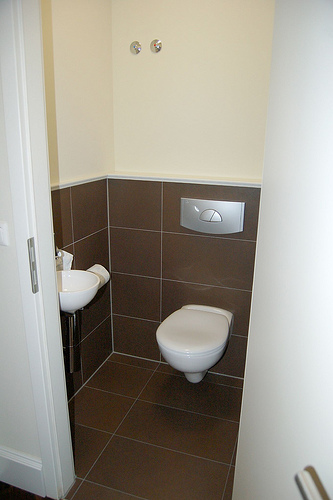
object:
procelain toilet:
[156, 303, 235, 383]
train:
[52, 245, 110, 322]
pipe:
[69, 312, 77, 374]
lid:
[155, 308, 229, 355]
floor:
[0, 353, 245, 499]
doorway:
[0, 0, 77, 499]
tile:
[49, 177, 262, 498]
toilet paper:
[83, 264, 111, 288]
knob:
[149, 38, 162, 53]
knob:
[129, 40, 141, 54]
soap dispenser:
[179, 196, 245, 235]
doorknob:
[289, 465, 332, 499]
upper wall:
[37, 0, 277, 186]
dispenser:
[179, 197, 246, 234]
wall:
[41, 174, 255, 386]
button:
[199, 209, 223, 224]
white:
[260, 93, 333, 398]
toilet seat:
[155, 308, 228, 358]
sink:
[56, 269, 101, 315]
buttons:
[130, 39, 162, 55]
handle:
[27, 237, 40, 294]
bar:
[294, 463, 333, 499]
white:
[156, 305, 235, 385]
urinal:
[55, 269, 100, 313]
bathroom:
[5, 0, 272, 499]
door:
[226, 0, 332, 492]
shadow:
[156, 369, 236, 433]